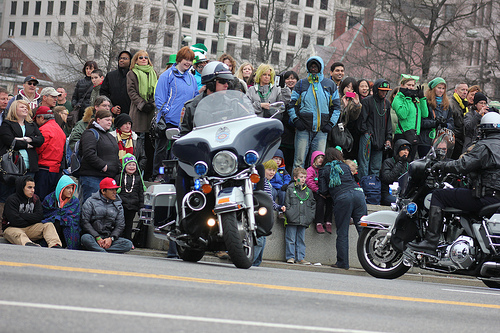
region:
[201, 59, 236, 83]
the helmet on the policeman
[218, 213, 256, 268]
the front wheel on the motorcycle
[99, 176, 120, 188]
the red hat on the man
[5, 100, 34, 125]
the blonde hair on the woman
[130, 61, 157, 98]
the green scarf on the woman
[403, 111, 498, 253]
the police officer on the motorcycle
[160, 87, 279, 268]
the motorcycle the police officer is riding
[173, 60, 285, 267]
man on a police motorcycle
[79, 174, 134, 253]
man sitting on a road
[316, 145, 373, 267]
woman wearing a blue scarf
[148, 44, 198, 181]
woman wearing a blue jacket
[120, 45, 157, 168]
woman wearing a green scarf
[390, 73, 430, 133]
woman wearing a green coat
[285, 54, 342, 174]
man wearing a hooded blue coat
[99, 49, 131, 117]
man wearing a hooded black coat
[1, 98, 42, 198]
blonde woman with a purse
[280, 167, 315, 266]
boy with green face paint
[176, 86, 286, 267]
a black and white police motorcycle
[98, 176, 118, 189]
a red baseball cap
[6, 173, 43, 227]
young man wearing a black sweatshirt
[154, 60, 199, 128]
woman wearing a light blue jacket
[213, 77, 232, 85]
police officer wearing sunglasses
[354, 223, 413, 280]
a black wheel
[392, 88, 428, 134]
young girl wearing a blue jacket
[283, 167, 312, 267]
a young boy on the street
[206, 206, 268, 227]
headlights of motorcycle is on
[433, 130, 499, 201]
police officer wearing a black jacket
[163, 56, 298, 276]
Police officer on a motor bike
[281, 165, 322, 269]
Boy with a shamrock necklace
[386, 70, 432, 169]
Woman in a green coat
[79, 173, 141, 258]
Man in a red baseball cap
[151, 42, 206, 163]
Red head boy in a blue coat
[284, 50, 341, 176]
Man with his hood pulled up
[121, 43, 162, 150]
Woman with a green scarf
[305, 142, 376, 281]
Woman taking care of a child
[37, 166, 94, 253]
Man with a blanket wrapped around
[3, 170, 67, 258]
Man with a black hooded sweatshirt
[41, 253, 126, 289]
The pavement has a yellow line.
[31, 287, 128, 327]
The pavement has a white line.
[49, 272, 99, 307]
The pavement is dark in color.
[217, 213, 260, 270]
The front motorcycle tire is black.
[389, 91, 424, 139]
The girl is wearing a green jacket.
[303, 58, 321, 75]
The man is wearing glasses.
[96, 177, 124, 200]
The man is wearing a red cap.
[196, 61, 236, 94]
The police officer is wearing sunglasses.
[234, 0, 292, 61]
The tree in the background is bare.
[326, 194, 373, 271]
The woman is wearing pants.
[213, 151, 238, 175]
the headlight on the motorcycle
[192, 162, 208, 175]
the blue light on the motorcycle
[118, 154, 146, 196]
the green hat on the child